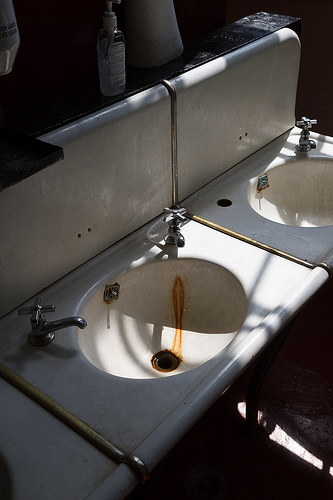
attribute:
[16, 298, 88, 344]
faucet — chrome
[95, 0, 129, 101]
soap — liquid, sitting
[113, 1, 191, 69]
paper towels — roll, sitting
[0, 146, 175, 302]
backsplash board — drilled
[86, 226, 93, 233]
hole — four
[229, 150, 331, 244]
sink — beige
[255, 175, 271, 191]
metal — rust coroded, green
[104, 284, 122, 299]
grate — coroded, metal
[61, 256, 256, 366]
sink bowl — double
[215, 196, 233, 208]
hole — small, black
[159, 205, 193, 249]
faucet — chrome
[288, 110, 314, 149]
handle — silver, water tap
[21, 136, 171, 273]
wall — porcelain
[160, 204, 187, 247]
handle — silver, water tap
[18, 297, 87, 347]
handle — silver, water tap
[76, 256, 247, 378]
bowl — white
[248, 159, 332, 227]
bowl — white